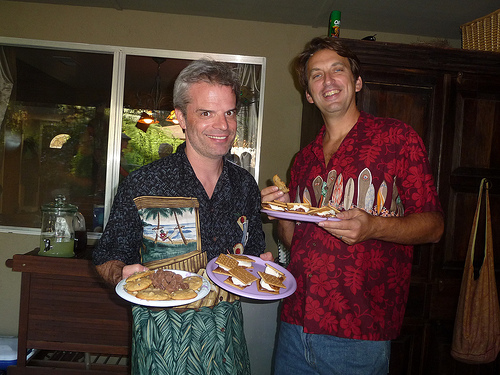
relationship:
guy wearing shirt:
[92, 53, 272, 374] [139, 160, 289, 362]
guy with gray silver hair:
[92, 53, 272, 374] [172, 51, 239, 116]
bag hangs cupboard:
[446, 171, 498, 367] [298, 39, 497, 373]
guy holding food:
[83, 51, 277, 372] [108, 253, 296, 308]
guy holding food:
[261, 38, 438, 371] [260, 194, 347, 225]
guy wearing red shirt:
[260, 36, 446, 374] [282, 112, 439, 219]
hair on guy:
[292, 39, 356, 85] [260, 36, 446, 374]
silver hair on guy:
[163, 57, 241, 116] [92, 53, 272, 374]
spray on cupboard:
[324, 6, 341, 38] [298, 37, 499, 374]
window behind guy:
[1, 35, 265, 240] [92, 53, 272, 374]